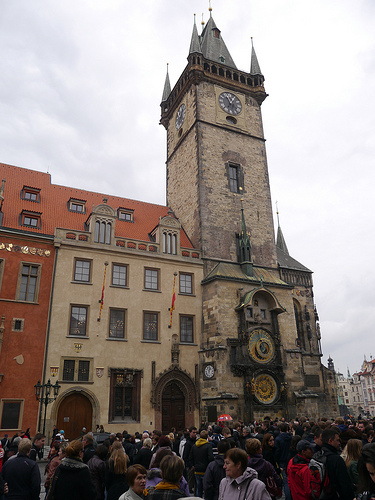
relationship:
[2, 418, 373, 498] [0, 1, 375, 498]
town square in czech republic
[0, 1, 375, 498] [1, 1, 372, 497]
czech republic in czech republic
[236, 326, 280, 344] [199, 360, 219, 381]
apostles beside clock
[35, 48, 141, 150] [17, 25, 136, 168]
clouds in sky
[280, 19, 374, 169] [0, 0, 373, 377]
clouds in sky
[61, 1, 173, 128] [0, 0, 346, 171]
clouds in sky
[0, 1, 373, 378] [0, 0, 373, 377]
clouds in sky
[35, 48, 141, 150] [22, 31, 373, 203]
clouds are in sky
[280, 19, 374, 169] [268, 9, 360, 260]
clouds are in sky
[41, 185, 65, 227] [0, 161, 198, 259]
tiles are on roof